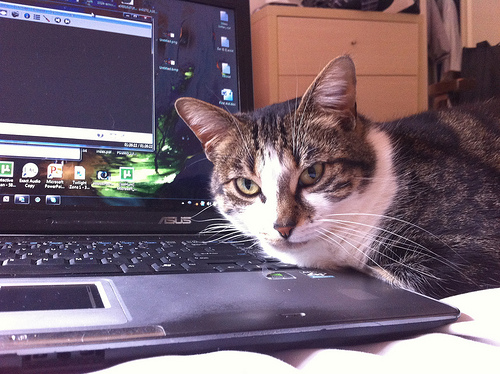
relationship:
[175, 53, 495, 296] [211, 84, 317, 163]
cat has whiskers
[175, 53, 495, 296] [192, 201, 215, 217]
cat has whisker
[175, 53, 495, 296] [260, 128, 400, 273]
cat has ruff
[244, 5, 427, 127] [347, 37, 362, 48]
cabinet has knob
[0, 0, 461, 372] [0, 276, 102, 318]
laptop has touchpad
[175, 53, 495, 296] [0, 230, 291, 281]
cat inspects keyboard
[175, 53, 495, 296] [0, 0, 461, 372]
cat facing computer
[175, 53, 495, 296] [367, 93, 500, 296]
cat has fur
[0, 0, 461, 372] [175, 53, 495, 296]
computer near cat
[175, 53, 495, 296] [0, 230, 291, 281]
cat touching keyboard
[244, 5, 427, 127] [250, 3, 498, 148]
cabinet in office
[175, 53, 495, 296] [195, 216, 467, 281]
cat has whiskers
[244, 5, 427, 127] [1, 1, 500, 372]
furniture in photo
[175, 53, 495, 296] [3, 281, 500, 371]
cat on desk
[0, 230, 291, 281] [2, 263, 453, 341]
keyboard has panel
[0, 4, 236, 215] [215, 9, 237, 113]
sceen has icons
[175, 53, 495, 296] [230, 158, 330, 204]
cat has eyes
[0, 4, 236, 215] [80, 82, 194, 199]
screen has swirl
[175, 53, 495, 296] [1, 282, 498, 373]
cat on blanket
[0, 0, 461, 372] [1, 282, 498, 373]
laptop on blanket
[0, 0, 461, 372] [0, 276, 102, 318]
laptop has trackpad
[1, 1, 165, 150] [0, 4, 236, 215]
window on screen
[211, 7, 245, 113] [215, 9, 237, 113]
row of icons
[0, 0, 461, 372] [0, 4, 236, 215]
laptop has screen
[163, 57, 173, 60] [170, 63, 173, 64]
pair of stickers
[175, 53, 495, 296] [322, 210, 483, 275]
cat has whisker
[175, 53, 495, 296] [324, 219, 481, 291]
cat has whisker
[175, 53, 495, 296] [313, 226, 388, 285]
cat has whisker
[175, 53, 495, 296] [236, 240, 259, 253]
cat has whisker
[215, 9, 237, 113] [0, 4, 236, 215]
icons on screen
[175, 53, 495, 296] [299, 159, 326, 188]
cat has eye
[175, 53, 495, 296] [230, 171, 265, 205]
cat has eyes